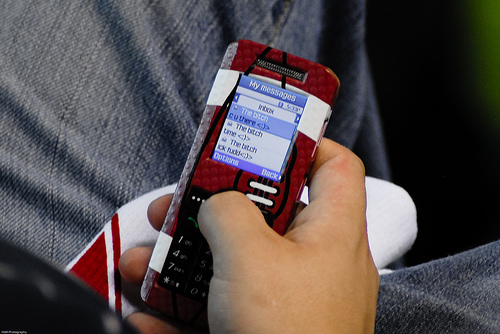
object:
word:
[257, 104, 274, 115]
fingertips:
[193, 186, 246, 223]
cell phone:
[140, 38, 342, 321]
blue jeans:
[1, 2, 500, 334]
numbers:
[166, 261, 176, 270]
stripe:
[250, 181, 279, 193]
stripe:
[243, 193, 275, 207]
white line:
[203, 65, 240, 107]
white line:
[148, 228, 173, 272]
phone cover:
[141, 40, 341, 318]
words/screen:
[210, 73, 309, 180]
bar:
[249, 180, 279, 193]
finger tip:
[146, 193, 173, 229]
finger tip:
[116, 242, 156, 283]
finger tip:
[125, 310, 164, 330]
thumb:
[194, 189, 292, 256]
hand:
[114, 134, 383, 332]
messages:
[222, 102, 296, 168]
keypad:
[157, 275, 182, 291]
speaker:
[257, 59, 305, 81]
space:
[371, 16, 498, 175]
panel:
[209, 73, 307, 183]